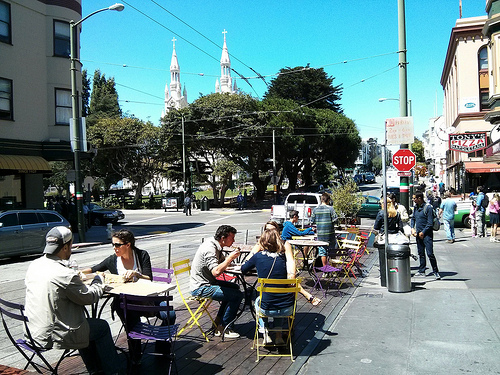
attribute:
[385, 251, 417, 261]
bag — black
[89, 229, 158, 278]
woman — sitting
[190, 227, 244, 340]
man — sitting, eating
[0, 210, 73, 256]
car — gray, parked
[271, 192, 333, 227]
truck — white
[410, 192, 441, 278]
man — standing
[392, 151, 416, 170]
sign — red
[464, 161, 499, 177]
awning — tan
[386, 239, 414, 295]
can — steel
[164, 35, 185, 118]
church — white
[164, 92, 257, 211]
trees — busy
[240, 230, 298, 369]
person — eating, dining, sitting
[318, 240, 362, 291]
chair — colored, purple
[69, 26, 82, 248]
pole — metal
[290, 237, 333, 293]
table — vacant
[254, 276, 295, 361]
chair — yellow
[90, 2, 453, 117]
sky — blue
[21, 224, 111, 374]
man — wearing cap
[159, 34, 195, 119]
spire — tall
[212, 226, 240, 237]
hair — dark